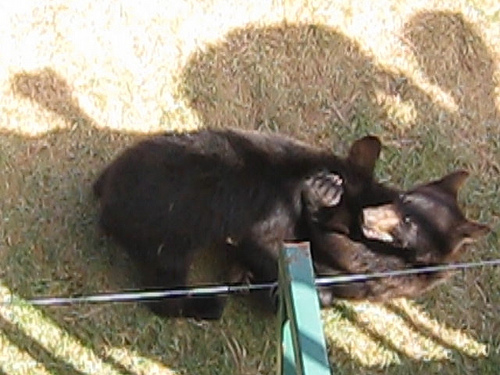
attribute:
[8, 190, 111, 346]
grass — dry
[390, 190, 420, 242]
eyes — black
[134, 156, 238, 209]
fur — black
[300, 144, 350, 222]
paws — black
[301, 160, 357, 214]
paws — black bear raising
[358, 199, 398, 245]
snout — cream colored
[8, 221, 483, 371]
fence — wire across 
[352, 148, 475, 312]
head — back 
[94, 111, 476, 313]
bear — black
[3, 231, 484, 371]
enclosure — green metal gate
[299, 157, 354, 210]
claws — large  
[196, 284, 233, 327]
paw — black bear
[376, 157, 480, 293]
head — bear's 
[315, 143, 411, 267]
head — bear's 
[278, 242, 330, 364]
pole — Wirel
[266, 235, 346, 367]
frame — Green metal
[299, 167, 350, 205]
paw — Large brown bear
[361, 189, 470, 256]
face — bear's 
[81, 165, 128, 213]
tail — Stubby brown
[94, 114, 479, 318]
cubs — Two bear, playing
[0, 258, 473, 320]
cable — Thick gray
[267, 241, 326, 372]
brace — metal 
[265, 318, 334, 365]
structure — Green metal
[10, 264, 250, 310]
deck — observation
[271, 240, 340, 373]
brace — green rectangular tubing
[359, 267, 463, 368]
shadow — dark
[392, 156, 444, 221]
bear — dark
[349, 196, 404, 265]
muzzle — brown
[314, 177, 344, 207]
paw — brown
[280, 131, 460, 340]
bear — black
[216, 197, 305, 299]
cubs — black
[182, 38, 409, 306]
bears — black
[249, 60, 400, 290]
bears — black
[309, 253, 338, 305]
post — black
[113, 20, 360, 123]
grass — green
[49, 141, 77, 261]
grass — green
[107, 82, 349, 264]
bears — black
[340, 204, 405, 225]
muzzle — brown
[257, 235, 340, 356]
post — green